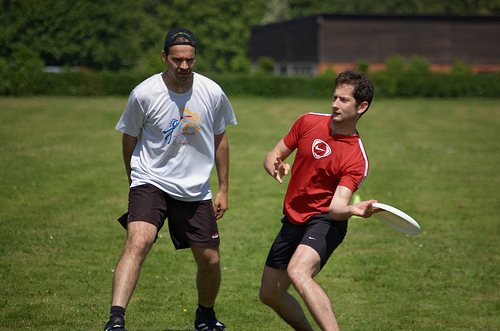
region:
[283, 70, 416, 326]
Man with red Nike shirt on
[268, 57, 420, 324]
Man holding a frisbee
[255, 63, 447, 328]
Man playing in the park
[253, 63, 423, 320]
Man with black Nike shorts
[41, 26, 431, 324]
Men playing together in the park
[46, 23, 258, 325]
Man with backwards cap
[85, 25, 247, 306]
Man with white t-shirt on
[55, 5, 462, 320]
Two men playing at work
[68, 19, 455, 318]
Adult men playing frisbee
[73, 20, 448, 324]
Two men with shorts playing frisbee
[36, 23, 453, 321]
two men on sports field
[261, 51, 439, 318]
man with red shirt and black shorts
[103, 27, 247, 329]
man with black hat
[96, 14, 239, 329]
man with black hat, white shirt, and black shorts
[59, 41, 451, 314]
two men playing Frisbee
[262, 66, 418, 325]
man catching white Frisbee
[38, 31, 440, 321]
two men on grassy flat field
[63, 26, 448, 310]
two men outside on grass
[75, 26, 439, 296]
two people playing Frisbee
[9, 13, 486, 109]
trees and building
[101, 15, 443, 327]
game of frisbee at the park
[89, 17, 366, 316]
men playing frisbee at the park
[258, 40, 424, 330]
white man throwing frisbee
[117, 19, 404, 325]
two white men laying frisbee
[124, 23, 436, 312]
game of ultimate frisbee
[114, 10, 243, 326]
man in white t-shirt and black shorts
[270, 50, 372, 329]
man in athletic clothes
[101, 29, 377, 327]
men in sportswear at the park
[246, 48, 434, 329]
man wearing red t-shirt and black shorts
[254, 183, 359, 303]
black nike athletic shorts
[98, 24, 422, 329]
two guys playing frisbee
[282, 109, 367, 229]
the man is wearing a red shirt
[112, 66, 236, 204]
a man is wearing a white t-shirt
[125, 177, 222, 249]
the shorts on the man are black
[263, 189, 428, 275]
the frisbee thrower's shorts are black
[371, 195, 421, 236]
the frisbee in the man's hand is white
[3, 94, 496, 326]
the field's grass is green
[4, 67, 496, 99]
a green hedge borders the field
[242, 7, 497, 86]
a building is behind the field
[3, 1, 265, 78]
green trees are behind the man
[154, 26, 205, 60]
the man is wearing a hat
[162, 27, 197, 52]
the hat is black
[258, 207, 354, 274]
the man is wearing shorts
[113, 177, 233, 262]
the man's shorts are black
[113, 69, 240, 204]
the man is wearing a white shirt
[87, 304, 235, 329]
the man is wearing black shoes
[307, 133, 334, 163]
the man has a logo on his shirt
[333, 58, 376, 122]
the man has short hair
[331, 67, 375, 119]
the man's hair is brown